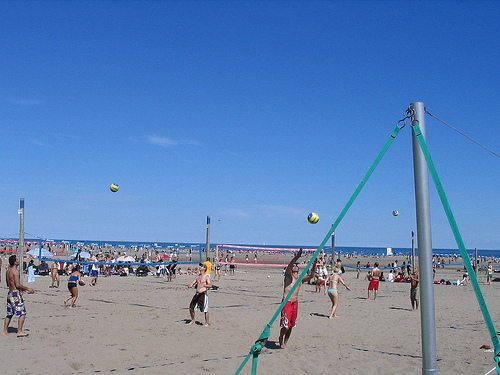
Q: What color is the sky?
A: Blue.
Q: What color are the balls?
A: Blue and yellow.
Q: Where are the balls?
A: In the air.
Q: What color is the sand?
A: Brown.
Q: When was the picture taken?
A: Daytime.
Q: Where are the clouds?
A: In the sky.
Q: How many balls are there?
A: Three.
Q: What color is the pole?
A: Silver.